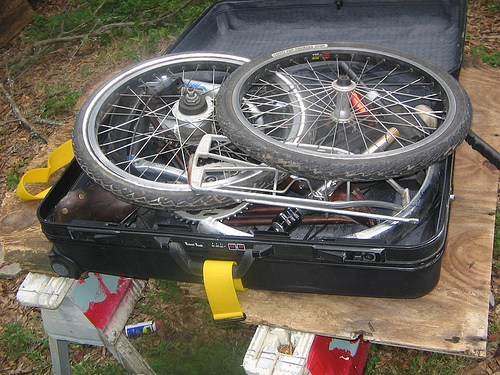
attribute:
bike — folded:
[72, 41, 473, 248]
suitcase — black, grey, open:
[36, 2, 468, 296]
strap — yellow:
[200, 260, 249, 324]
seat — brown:
[57, 175, 137, 218]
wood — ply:
[1, 68, 498, 359]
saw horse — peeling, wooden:
[15, 272, 159, 371]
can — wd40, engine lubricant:
[121, 321, 164, 334]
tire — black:
[218, 39, 473, 179]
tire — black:
[72, 46, 318, 206]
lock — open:
[184, 239, 247, 252]